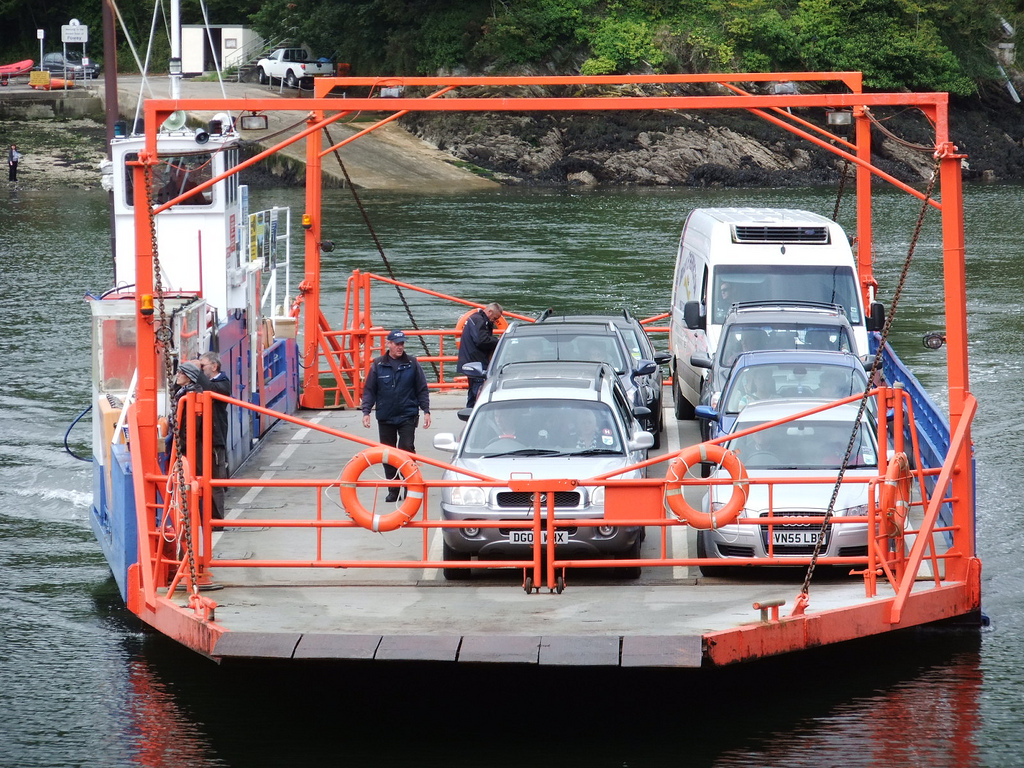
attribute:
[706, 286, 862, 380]
suv — grey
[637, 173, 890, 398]
van — white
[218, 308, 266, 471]
doors — blue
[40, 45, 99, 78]
car —  Black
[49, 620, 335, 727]
water — murky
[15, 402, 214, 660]
water — rippled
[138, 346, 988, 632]
gate — orange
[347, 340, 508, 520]
man — standing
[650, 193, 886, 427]
van — large, white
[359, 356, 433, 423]
jacket — blue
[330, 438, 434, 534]
safety donut — orange